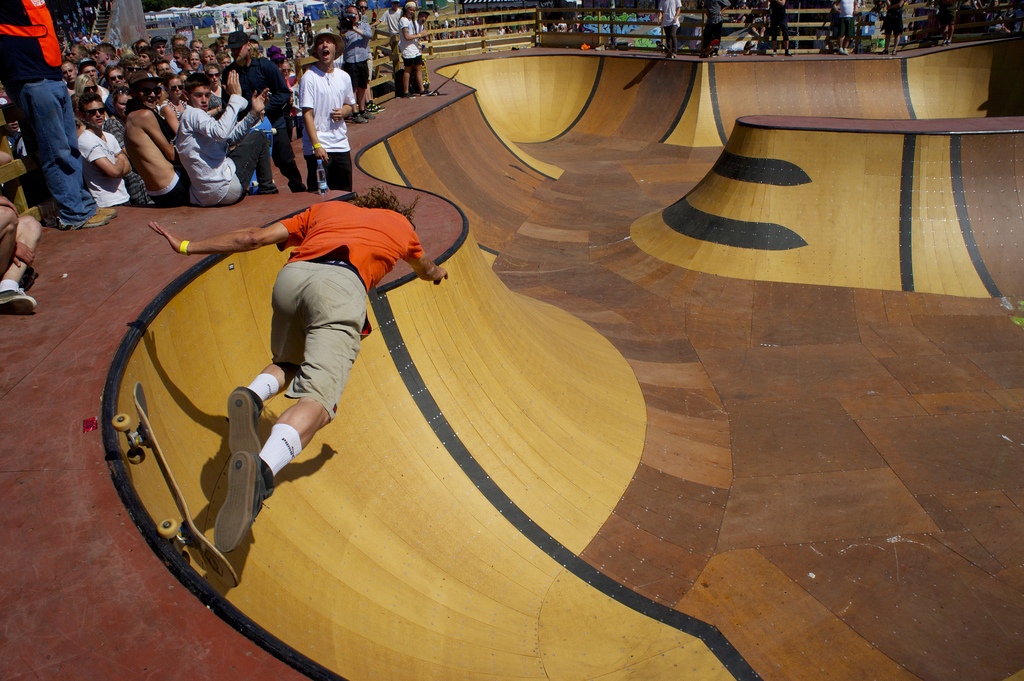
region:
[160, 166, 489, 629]
boy is skating in a skatepark.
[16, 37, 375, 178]
Kids are watching the skateboarder.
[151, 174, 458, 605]
skateboader doing a trick on ramp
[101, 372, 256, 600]
skateboard on a ramp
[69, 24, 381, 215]
crowd at a skatepark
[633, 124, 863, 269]
design on a ramp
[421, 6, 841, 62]
fence at a skatepark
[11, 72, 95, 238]
jeans on a man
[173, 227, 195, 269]
bracelet on a wrist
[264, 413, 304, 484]
white sock on a man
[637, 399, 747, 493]
wooden panel on a ramp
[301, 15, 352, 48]
hat on a spectator in crowd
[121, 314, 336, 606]
The shadow of the skateboarder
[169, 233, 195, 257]
The yellow wristband on the skateboarder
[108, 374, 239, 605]
The skateboard currently being ridden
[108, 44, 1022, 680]
The wooden skateboaring course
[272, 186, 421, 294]
The skateboarder's orange shirt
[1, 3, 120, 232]
The person in blue jeans and an orange vest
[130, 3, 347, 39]
The tents beyond the wood railing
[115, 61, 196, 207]
The man with no shirt on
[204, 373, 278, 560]
The shoes of the man skateboarding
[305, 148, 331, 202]
The water bottle sitting on the ramp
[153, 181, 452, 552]
the man is falling down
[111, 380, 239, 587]
the skateboard has wheels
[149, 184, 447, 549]
the man is wearing an orange shirt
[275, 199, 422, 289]
the shirt is orange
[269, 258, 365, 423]
the shorts are brown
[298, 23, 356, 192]
the man has his mouth opened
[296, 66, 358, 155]
the shirt is white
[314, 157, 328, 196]
the plastic bottle of water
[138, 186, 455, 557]
the man falling off the skateboard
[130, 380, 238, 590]
the skateboard on the rail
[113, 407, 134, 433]
the front left wheel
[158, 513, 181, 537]
the rear left wheel on the skateboard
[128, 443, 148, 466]
the right front wheel of the skateboard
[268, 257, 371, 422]
the shorts are tan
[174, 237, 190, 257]
the yellow band on the mans wrist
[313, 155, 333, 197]
the water bottle on the ramp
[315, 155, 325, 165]
the blue lid of the bottle